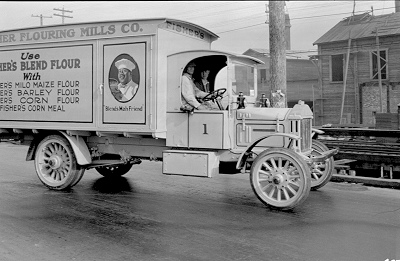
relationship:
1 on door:
[201, 121, 209, 134] [186, 111, 223, 149]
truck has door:
[1, 16, 335, 210] [186, 111, 223, 149]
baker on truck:
[105, 50, 144, 104] [1, 16, 335, 210]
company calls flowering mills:
[1, 11, 145, 42] [19, 19, 119, 47]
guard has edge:
[231, 151, 258, 175] [232, 147, 248, 168]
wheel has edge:
[223, 142, 317, 214] [295, 161, 314, 198]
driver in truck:
[179, 64, 227, 109] [1, 16, 335, 210]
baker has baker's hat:
[107, 58, 138, 102] [111, 56, 133, 70]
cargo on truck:
[27, 22, 169, 124] [1, 16, 335, 210]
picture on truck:
[107, 51, 139, 101] [1, 16, 335, 210]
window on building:
[329, 52, 342, 82] [313, 0, 398, 184]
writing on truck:
[0, 52, 81, 110] [1, 16, 335, 210]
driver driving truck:
[179, 64, 224, 109] [1, 16, 335, 210]